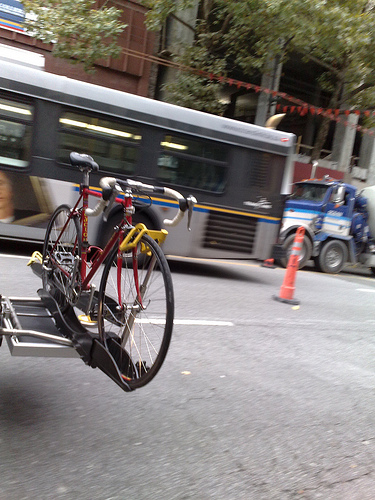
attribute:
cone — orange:
[260, 206, 324, 317]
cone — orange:
[268, 216, 321, 318]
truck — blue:
[255, 148, 363, 284]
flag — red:
[226, 76, 235, 86]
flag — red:
[235, 79, 241, 90]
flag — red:
[252, 80, 260, 95]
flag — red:
[272, 101, 281, 112]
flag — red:
[287, 103, 297, 114]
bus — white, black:
[7, 62, 284, 262]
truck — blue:
[271, 159, 373, 249]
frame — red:
[73, 181, 149, 307]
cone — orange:
[273, 227, 305, 306]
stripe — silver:
[291, 241, 302, 247]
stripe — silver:
[289, 250, 299, 255]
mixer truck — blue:
[287, 178, 372, 276]